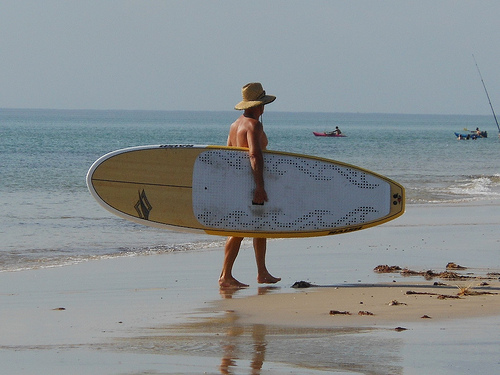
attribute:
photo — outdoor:
[0, 2, 497, 374]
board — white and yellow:
[102, 139, 414, 244]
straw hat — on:
[232, 80, 278, 111]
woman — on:
[328, 126, 343, 136]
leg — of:
[251, 236, 281, 286]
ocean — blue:
[0, 115, 496, 253]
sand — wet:
[1, 200, 499, 372]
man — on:
[211, 57, 292, 296]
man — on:
[224, 73, 277, 287]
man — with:
[219, 81, 276, 288]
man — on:
[217, 77, 290, 311]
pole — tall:
[465, 46, 498, 121]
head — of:
[238, 77, 299, 116]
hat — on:
[223, 74, 299, 119]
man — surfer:
[163, 50, 381, 237]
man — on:
[216, 83, 281, 291]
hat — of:
[235, 82, 277, 110]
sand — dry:
[206, 268, 498, 324]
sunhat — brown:
[232, 81, 276, 111]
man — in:
[329, 125, 344, 137]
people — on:
[325, 116, 342, 136]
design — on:
[266, 198, 387, 238]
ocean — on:
[12, 226, 81, 275]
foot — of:
[216, 267, 252, 292]